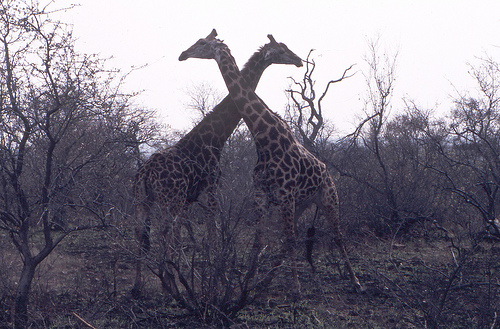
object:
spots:
[241, 97, 262, 120]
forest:
[0, 0, 500, 329]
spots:
[296, 148, 314, 163]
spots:
[146, 162, 175, 195]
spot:
[284, 152, 292, 167]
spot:
[302, 157, 310, 167]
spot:
[304, 177, 315, 186]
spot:
[283, 178, 295, 188]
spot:
[260, 136, 268, 148]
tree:
[465, 107, 497, 227]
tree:
[354, 36, 394, 248]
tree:
[285, 47, 357, 149]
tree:
[150, 224, 197, 306]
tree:
[1, 8, 27, 320]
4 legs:
[278, 192, 302, 303]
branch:
[35, 203, 126, 293]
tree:
[187, 84, 213, 115]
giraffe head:
[178, 28, 224, 62]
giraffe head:
[262, 34, 304, 68]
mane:
[240, 45, 262, 71]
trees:
[256, 230, 285, 280]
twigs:
[389, 286, 498, 329]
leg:
[315, 193, 365, 295]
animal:
[175, 28, 367, 306]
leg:
[242, 186, 271, 298]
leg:
[278, 195, 301, 303]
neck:
[212, 54, 279, 155]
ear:
[205, 28, 218, 39]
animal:
[131, 34, 303, 304]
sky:
[126, 1, 484, 97]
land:
[0, 207, 500, 329]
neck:
[185, 61, 275, 148]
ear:
[264, 47, 278, 61]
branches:
[15, 60, 127, 136]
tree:
[54, 144, 109, 216]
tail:
[139, 169, 154, 254]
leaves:
[44, 102, 461, 152]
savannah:
[0, 0, 500, 329]